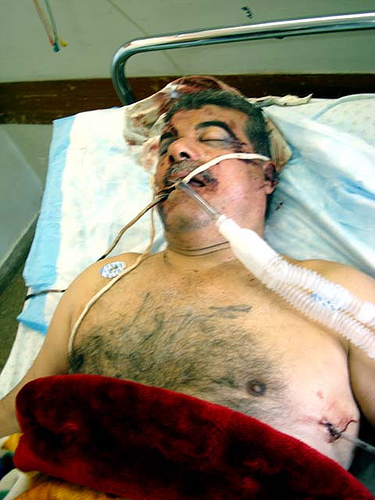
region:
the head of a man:
[145, 82, 290, 259]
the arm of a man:
[0, 272, 88, 439]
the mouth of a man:
[158, 167, 214, 199]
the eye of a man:
[195, 123, 235, 149]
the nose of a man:
[164, 125, 202, 168]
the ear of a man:
[258, 158, 283, 200]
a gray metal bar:
[106, 9, 374, 110]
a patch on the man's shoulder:
[98, 256, 129, 282]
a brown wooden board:
[0, 68, 374, 133]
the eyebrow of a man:
[190, 118, 238, 139]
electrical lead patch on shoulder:
[92, 250, 128, 283]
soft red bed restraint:
[5, 370, 370, 499]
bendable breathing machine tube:
[163, 167, 374, 368]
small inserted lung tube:
[289, 388, 374, 461]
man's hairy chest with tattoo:
[49, 242, 307, 435]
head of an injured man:
[117, 77, 295, 266]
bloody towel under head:
[102, 53, 310, 212]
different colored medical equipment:
[24, 2, 86, 65]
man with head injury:
[92, 54, 327, 270]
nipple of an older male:
[228, 364, 277, 407]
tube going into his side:
[304, 412, 371, 453]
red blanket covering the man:
[41, 359, 269, 482]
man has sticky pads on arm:
[105, 246, 140, 278]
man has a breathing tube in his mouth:
[170, 162, 200, 208]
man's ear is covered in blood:
[257, 155, 284, 208]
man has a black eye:
[155, 134, 176, 159]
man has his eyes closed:
[137, 122, 253, 158]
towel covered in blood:
[108, 69, 229, 152]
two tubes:
[240, 259, 373, 317]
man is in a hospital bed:
[60, 92, 371, 365]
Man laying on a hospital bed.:
[9, 3, 370, 493]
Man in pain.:
[81, 63, 318, 276]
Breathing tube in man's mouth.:
[145, 144, 269, 273]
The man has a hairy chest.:
[64, 267, 285, 443]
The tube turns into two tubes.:
[164, 174, 373, 376]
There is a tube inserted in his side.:
[273, 371, 372, 452]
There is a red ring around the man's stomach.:
[3, 350, 359, 495]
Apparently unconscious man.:
[29, 49, 344, 253]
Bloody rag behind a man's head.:
[72, 45, 329, 285]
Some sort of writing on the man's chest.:
[93, 273, 272, 361]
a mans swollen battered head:
[148, 91, 276, 250]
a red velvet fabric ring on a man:
[10, 376, 370, 497]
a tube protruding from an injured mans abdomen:
[324, 418, 372, 451]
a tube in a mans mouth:
[171, 180, 371, 355]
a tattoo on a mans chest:
[131, 289, 252, 340]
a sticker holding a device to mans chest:
[94, 262, 125, 281]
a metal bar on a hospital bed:
[98, 9, 372, 97]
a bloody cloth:
[124, 73, 246, 140]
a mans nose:
[165, 136, 201, 164]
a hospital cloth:
[42, 114, 374, 296]